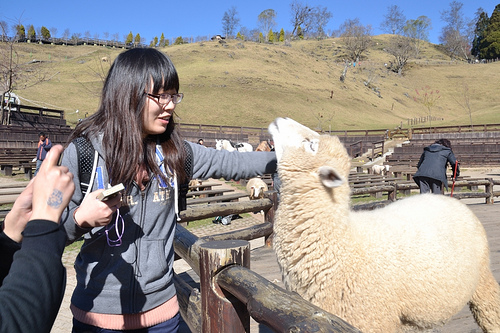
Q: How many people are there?
A: 3.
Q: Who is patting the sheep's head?
A: A lady.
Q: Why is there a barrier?
A: To stop the sheep going out.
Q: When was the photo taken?
A: Day time.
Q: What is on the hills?
A: Trees.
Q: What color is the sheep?
A: White.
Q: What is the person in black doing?
A: Taking the sheep a photo.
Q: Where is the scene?
A: At the zoo.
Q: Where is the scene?
A: A petting zoo.